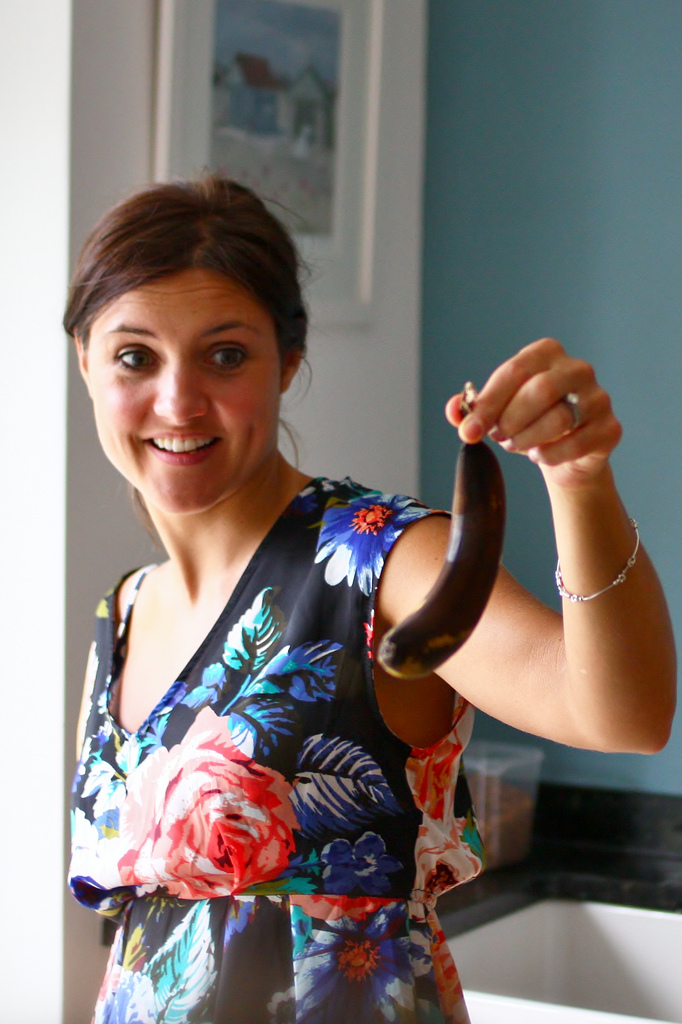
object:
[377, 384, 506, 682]
banana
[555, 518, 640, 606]
bracelet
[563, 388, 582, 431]
ring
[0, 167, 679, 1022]
she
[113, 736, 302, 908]
flower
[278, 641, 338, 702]
blue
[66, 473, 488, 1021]
dress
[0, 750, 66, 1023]
wall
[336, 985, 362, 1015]
blue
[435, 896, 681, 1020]
sink